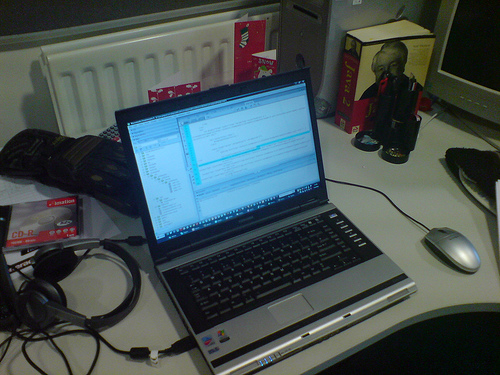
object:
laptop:
[115, 69, 415, 374]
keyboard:
[161, 208, 380, 333]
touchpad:
[264, 293, 321, 324]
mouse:
[424, 227, 481, 274]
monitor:
[115, 69, 328, 260]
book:
[335, 20, 437, 135]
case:
[1, 193, 79, 254]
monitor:
[434, 0, 499, 113]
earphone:
[14, 240, 142, 329]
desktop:
[273, 0, 425, 118]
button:
[356, 240, 367, 248]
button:
[351, 235, 363, 245]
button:
[343, 227, 355, 235]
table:
[3, 93, 499, 375]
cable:
[0, 310, 171, 374]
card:
[250, 48, 278, 83]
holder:
[360, 74, 422, 163]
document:
[126, 89, 323, 245]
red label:
[41, 193, 80, 207]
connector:
[165, 336, 197, 356]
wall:
[0, 47, 50, 135]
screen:
[122, 82, 326, 246]